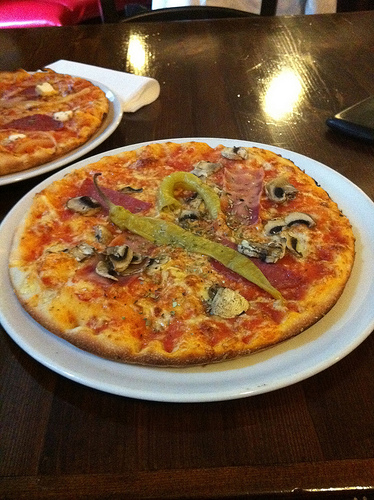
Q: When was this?
A: Daytime.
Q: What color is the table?
A: Brown.